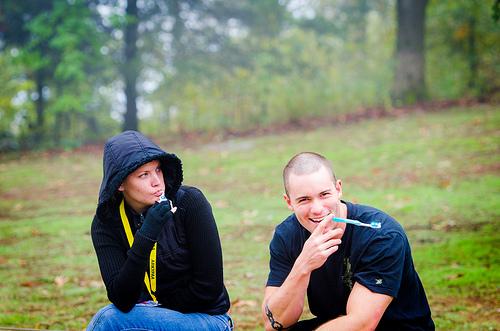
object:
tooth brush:
[332, 217, 381, 229]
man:
[264, 151, 436, 331]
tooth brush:
[159, 190, 166, 200]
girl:
[83, 131, 231, 331]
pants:
[81, 303, 230, 331]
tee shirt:
[267, 200, 436, 331]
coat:
[90, 130, 231, 315]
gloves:
[140, 200, 174, 239]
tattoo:
[265, 298, 284, 331]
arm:
[262, 234, 309, 331]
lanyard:
[119, 201, 157, 304]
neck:
[124, 194, 148, 215]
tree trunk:
[389, 0, 425, 107]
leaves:
[181, 94, 499, 146]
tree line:
[0, 0, 500, 149]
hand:
[145, 200, 177, 230]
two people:
[84, 131, 437, 331]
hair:
[284, 151, 337, 198]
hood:
[97, 131, 184, 207]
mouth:
[153, 189, 165, 198]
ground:
[0, 104, 500, 330]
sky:
[94, 1, 219, 121]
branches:
[140, 6, 411, 59]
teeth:
[312, 215, 328, 221]